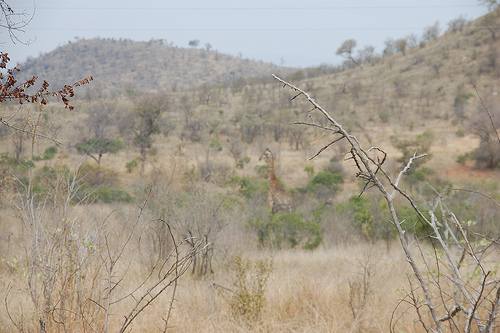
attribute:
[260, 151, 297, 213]
giraffe — blurry, standing, alone, camouflaged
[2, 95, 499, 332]
field — green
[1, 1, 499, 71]
sky — blue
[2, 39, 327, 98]
hill — rolling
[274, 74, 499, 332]
tree — dried, dead, leaning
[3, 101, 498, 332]
grass — dried, dry, brown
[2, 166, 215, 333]
bush — leafless, dry, green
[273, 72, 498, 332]
plant — dead, dried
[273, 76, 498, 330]
twig — brownish, dry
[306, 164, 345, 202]
shrub — green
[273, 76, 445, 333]
branch — dead